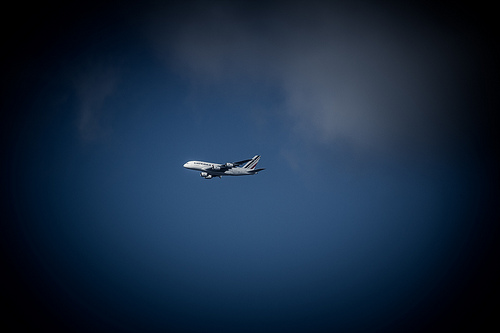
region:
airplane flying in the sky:
[174, 129, 271, 207]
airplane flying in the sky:
[175, 126, 275, 195]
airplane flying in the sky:
[162, 126, 285, 203]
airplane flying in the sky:
[173, 129, 279, 203]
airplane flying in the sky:
[175, 139, 277, 206]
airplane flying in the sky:
[179, 138, 279, 200]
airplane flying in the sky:
[170, 137, 275, 199]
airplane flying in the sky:
[175, 135, 269, 202]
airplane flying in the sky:
[172, 131, 279, 208]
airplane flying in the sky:
[181, 135, 283, 195]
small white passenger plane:
[181, 153, 265, 180]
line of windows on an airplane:
[192, 160, 214, 166]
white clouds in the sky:
[7, 3, 479, 150]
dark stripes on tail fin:
[243, 153, 261, 170]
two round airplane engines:
[197, 170, 212, 178]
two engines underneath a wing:
[210, 158, 251, 172]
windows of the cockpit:
[183, 159, 190, 165]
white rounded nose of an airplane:
[181, 162, 188, 169]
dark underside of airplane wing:
[206, 157, 252, 172]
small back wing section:
[246, 166, 264, 175]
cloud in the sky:
[281, 27, 481, 147]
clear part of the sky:
[294, 151, 421, 268]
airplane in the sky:
[175, 142, 270, 194]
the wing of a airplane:
[213, 159, 255, 175]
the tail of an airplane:
[241, 148, 265, 173]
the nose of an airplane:
[179, 149, 201, 174]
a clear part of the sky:
[86, 175, 206, 295]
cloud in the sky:
[156, 30, 234, 85]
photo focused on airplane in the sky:
[0, 4, 499, 329]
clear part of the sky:
[157, 92, 267, 147]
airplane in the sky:
[180, 150, 265, 180]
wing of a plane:
[210, 155, 245, 170]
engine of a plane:
[220, 160, 235, 170]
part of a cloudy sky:
[165, 45, 385, 140]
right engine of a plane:
[195, 170, 205, 175]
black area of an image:
[430, 10, 490, 60]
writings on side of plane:
[190, 155, 205, 165]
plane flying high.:
[170, 145, 280, 190]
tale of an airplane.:
[244, 149, 264, 172]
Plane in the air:
[179, 144, 269, 191]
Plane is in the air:
[180, 152, 263, 181]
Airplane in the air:
[176, 150, 269, 179]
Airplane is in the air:
[179, 145, 264, 183]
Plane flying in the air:
[181, 147, 267, 178]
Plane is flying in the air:
[175, 147, 266, 182]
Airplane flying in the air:
[177, 148, 272, 181]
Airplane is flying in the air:
[177, 151, 267, 181]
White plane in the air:
[180, 147, 265, 179]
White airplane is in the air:
[177, 148, 269, 178]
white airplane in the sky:
[176, 152, 257, 189]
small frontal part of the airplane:
[186, 160, 194, 170]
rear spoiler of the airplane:
[248, 155, 262, 180]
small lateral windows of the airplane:
[193, 159, 212, 169]